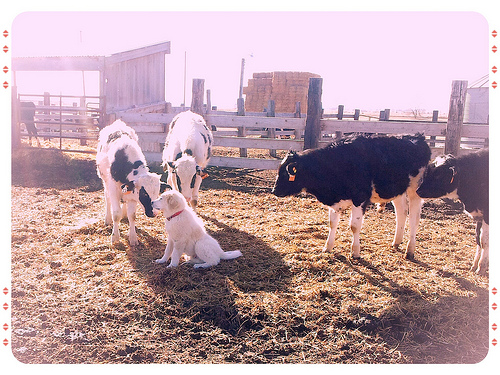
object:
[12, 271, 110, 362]
straw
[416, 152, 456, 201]
head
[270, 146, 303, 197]
head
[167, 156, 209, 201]
head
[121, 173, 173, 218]
head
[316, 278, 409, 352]
dirt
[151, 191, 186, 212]
head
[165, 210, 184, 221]
collar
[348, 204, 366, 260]
legs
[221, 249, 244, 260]
tail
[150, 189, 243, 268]
animal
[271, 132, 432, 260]
animal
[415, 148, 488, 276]
animal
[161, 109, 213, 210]
animal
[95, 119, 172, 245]
animal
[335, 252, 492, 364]
shadow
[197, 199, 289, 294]
shadow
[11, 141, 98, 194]
shadow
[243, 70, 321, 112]
straw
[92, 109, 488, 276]
animals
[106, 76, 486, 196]
fence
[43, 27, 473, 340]
photo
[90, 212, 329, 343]
ground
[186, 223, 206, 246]
fur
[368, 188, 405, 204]
belly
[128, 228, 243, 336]
shadow